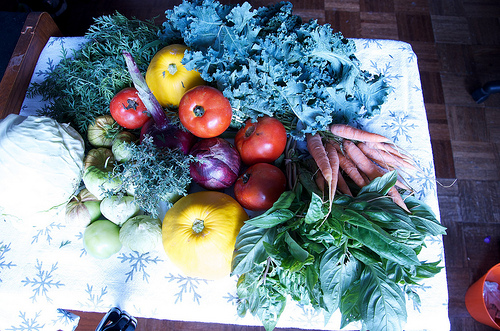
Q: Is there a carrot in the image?
A: Yes, there are carrots.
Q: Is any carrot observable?
A: Yes, there are carrots.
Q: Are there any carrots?
A: Yes, there are carrots.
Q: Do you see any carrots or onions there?
A: Yes, there are carrots.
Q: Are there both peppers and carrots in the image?
A: No, there are carrots but no peppers.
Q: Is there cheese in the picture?
A: No, there is no cheese.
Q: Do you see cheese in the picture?
A: No, there is no cheese.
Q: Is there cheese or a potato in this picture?
A: No, there are no cheese or potatoes.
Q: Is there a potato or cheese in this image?
A: No, there are no cheese or potatoes.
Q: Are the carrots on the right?
A: Yes, the carrots are on the right of the image.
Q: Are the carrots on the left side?
A: No, the carrots are on the right of the image.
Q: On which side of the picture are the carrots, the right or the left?
A: The carrots are on the right of the image.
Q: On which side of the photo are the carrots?
A: The carrots are on the right of the image.